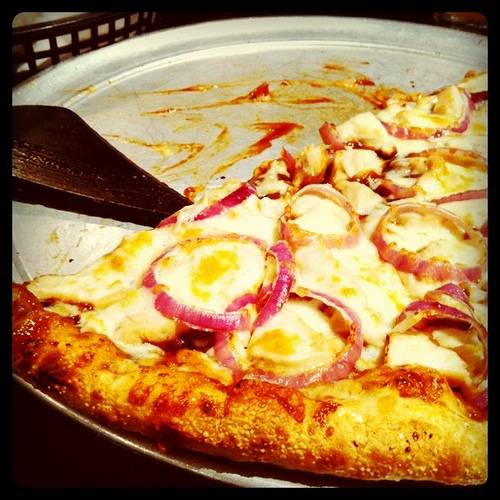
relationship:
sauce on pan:
[114, 55, 400, 197] [13, 10, 487, 490]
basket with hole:
[3, 1, 158, 78] [96, 22, 110, 34]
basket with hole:
[3, 1, 158, 78] [29, 37, 52, 52]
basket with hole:
[3, 1, 158, 78] [126, 12, 141, 27]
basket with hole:
[3, 1, 158, 78] [53, 31, 74, 48]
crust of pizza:
[3, 284, 499, 484] [10, 66, 487, 489]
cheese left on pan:
[13, 72, 489, 485] [10, 16, 487, 490]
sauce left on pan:
[63, 57, 441, 201] [10, 16, 487, 490]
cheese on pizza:
[26, 67, 489, 389] [10, 66, 487, 489]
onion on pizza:
[128, 206, 360, 376] [10, 66, 487, 489]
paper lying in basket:
[12, 9, 157, 69] [21, 17, 103, 57]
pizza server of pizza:
[11, 105, 194, 228] [10, 66, 487, 489]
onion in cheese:
[141, 233, 293, 330] [26, 67, 489, 389]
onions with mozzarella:
[193, 144, 357, 319] [68, 45, 481, 418]